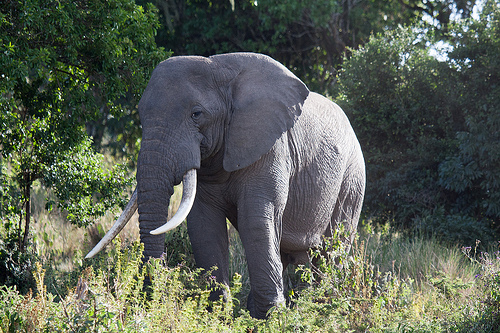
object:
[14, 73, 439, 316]
area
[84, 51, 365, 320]
elephant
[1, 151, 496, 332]
clearing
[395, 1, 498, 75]
patch of sky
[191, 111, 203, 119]
eye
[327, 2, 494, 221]
trees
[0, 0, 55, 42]
leaves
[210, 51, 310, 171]
ear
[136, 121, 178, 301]
trunk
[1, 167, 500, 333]
grass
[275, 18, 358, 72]
dead branches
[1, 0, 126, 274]
tree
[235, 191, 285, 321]
leg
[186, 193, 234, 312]
leg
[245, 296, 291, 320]
foot